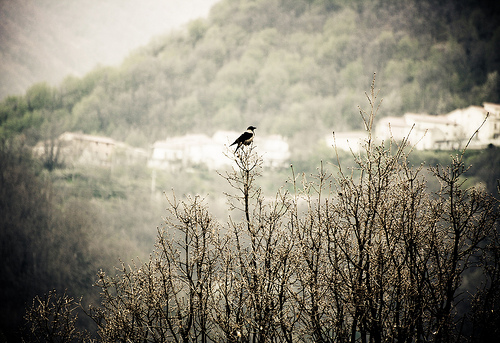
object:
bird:
[228, 125, 258, 154]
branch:
[222, 155, 261, 254]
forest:
[143, 52, 263, 129]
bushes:
[0, 140, 93, 317]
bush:
[188, 240, 500, 343]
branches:
[321, 108, 478, 341]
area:
[123, 15, 430, 133]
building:
[324, 102, 497, 156]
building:
[150, 125, 285, 163]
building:
[30, 126, 150, 183]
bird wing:
[237, 131, 254, 141]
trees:
[0, 0, 498, 143]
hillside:
[3, 1, 499, 341]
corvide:
[230, 122, 255, 152]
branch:
[224, 143, 264, 340]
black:
[228, 132, 254, 152]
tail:
[232, 142, 242, 153]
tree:
[0, 142, 500, 339]